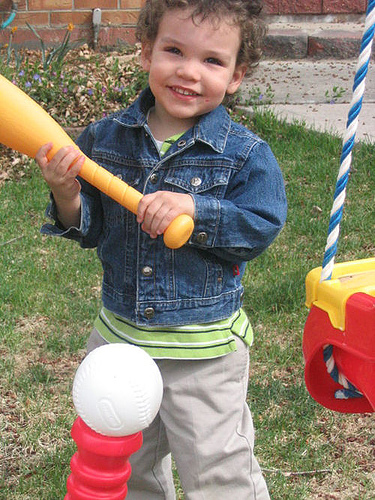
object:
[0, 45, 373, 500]
ground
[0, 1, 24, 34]
water hose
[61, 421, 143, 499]
tee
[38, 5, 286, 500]
boy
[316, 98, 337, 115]
ground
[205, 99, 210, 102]
mark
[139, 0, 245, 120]
face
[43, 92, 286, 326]
jacket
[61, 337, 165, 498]
toy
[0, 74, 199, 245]
bat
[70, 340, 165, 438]
ball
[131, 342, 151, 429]
design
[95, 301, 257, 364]
shirt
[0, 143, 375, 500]
grass ground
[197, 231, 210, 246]
button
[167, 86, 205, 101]
teeth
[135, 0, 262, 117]
happy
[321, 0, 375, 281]
line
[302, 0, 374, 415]
toy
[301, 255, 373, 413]
swing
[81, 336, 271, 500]
pants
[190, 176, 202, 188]
button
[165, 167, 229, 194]
pocket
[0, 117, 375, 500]
grass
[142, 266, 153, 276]
button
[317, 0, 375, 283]
rope